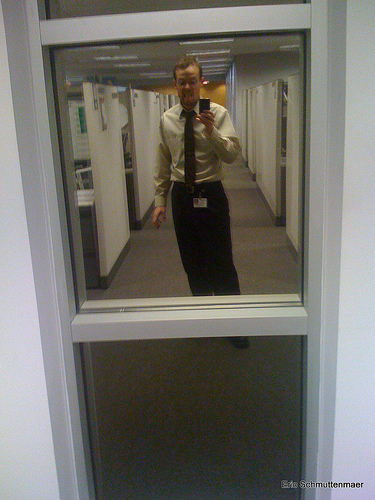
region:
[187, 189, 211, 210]
Identification badge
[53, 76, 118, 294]
Inside of an office cubicle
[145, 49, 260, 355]
A man taking a self portrait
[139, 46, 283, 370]
A man taking a picture of himself in his office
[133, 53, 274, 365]
Self photo being taken by a man in front of a mirror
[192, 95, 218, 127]
Black cell phone being held by a hand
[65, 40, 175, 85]
Five florescent lights in the ceiling of an office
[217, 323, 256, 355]
Black shoe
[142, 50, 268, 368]
Male in business casual taking a photo of himself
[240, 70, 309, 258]
Entrance to three cubicles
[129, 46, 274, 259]
Man holding a phone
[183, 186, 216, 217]
Man is wearing a white badge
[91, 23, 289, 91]
Row of lights on the ceiling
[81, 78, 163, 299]
White cubicle walls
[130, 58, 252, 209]
Man is wearing a white shirt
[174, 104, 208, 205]
Man is wearing a dark tie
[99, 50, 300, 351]
The man is standing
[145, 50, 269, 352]
The man is taking a picture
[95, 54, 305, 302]
The man is in between the cubicles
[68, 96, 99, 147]
Blue paper on wall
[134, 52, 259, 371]
man sticking out tongue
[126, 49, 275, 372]
man holding black cell phone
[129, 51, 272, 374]
man holding square phone with camera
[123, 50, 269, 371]
man taking a picture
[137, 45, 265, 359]
man wearing collared shirt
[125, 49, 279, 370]
man wearing long sleeve shirt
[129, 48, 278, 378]
man wearing identification badge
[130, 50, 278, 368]
man wearing light colored button-up shirt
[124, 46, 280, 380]
man wearing necktie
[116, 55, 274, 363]
man wearing dark pants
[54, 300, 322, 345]
double pane window frame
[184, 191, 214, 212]
personal work identification card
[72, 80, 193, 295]
cubicles in an office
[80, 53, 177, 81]
over head fluorescent lighting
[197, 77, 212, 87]
exit sign at end of hallway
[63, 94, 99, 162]
calender in a work cubical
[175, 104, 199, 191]
man wearing black neck tie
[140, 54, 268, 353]
man walking down a hallway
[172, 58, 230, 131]
man looking at cell phone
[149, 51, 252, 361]
man wearing dress clothes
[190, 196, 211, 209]
a name tag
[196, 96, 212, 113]
a black cellphone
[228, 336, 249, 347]
part of a man's shoe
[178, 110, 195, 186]
a man's long tie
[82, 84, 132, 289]
the wall of a cubicle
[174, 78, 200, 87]
a man's eyeglasses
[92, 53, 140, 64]
a ceiling light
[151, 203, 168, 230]
the hand of a man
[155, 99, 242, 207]
a man's long sleeve shirt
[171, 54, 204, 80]
a man's short cut hair